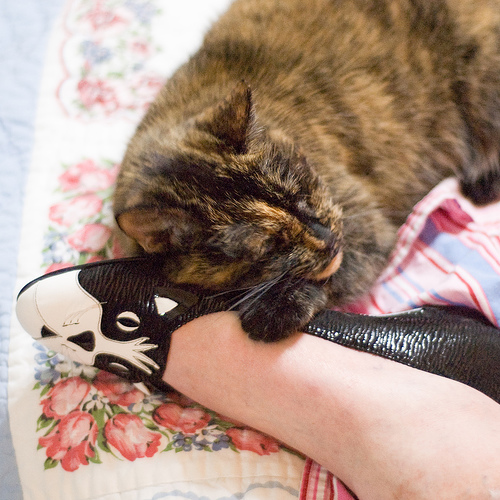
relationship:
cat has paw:
[119, 2, 499, 345] [239, 276, 331, 343]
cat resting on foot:
[119, 2, 499, 345] [20, 247, 498, 499]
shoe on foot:
[19, 247, 498, 399] [20, 247, 498, 499]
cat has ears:
[119, 2, 499, 345] [111, 74, 261, 247]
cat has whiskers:
[119, 2, 499, 345] [184, 270, 314, 309]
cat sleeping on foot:
[119, 2, 499, 345] [20, 247, 498, 499]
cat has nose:
[119, 2, 499, 345] [302, 225, 335, 247]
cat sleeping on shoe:
[119, 2, 499, 345] [19, 247, 498, 399]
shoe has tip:
[19, 247, 498, 399] [9, 278, 126, 365]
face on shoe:
[37, 282, 160, 366] [19, 247, 498, 399]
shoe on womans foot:
[19, 247, 498, 399] [20, 247, 498, 499]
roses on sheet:
[20, 356, 291, 487] [4, 1, 178, 284]